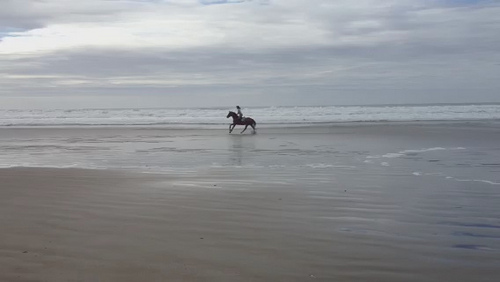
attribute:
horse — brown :
[220, 102, 260, 142]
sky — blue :
[1, 12, 498, 104]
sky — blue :
[5, 7, 488, 129]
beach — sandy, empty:
[2, 116, 495, 278]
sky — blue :
[292, 39, 456, 101]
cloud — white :
[2, 2, 150, 39]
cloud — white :
[2, 42, 362, 87]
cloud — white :
[371, 5, 498, 100]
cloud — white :
[304, 3, 378, 38]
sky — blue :
[154, 29, 311, 52]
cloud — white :
[3, 3, 411, 69]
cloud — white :
[4, 1, 395, 64]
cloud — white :
[0, 4, 377, 61]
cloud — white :
[3, 5, 413, 81]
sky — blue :
[2, 1, 498, 106]